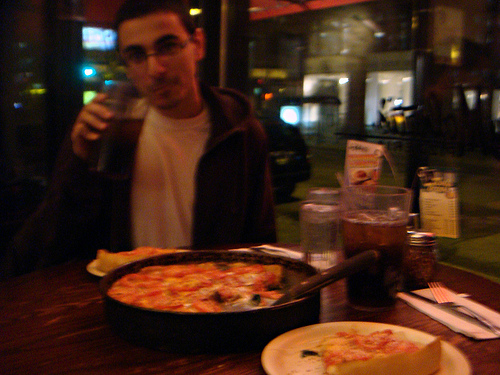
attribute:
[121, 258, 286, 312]
pizza — deep dish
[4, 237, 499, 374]
table — wood, woode, wooden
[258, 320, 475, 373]
plate — white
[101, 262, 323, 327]
dish — deep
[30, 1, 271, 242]
man — perso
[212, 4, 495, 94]
background — blurry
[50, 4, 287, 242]
guy — eating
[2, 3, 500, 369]
picture — blurry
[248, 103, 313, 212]
car — parked